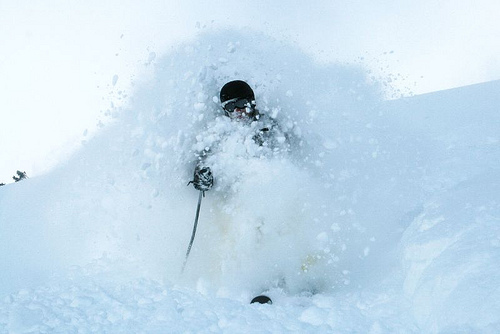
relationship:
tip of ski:
[228, 288, 281, 312] [234, 267, 342, 316]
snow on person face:
[217, 96, 254, 131] [225, 97, 254, 124]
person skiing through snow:
[194, 80, 294, 191] [90, 24, 414, 300]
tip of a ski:
[250, 294, 273, 305] [238, 291, 281, 307]